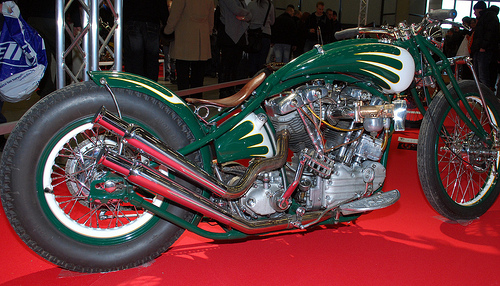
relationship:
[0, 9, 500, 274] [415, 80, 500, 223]
bike has tire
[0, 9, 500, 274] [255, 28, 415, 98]
bike has tank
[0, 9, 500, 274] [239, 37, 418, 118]
bike has tank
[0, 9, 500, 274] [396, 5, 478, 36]
bike has handle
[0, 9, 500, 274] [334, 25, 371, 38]
bike has handle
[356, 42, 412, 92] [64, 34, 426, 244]
design on bike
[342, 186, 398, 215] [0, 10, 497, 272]
foot support on bike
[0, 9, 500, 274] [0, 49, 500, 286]
bike displayed on platform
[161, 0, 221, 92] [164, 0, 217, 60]
person wearing coat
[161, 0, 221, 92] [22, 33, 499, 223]
person behind bike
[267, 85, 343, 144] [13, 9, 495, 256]
engine of motorcycle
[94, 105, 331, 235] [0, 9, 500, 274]
muffler on bike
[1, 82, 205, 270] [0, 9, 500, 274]
tire on bike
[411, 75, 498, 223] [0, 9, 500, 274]
tire on bike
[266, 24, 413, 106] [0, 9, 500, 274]
fuel tank on bike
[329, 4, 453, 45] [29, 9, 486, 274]
handlebars on motorcycle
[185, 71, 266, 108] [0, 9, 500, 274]
seat on bike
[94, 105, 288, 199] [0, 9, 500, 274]
muffler on bike